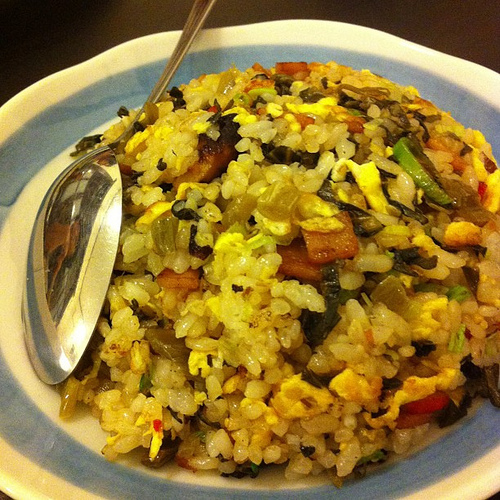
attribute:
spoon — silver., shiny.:
[22, 2, 215, 385]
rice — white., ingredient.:
[57, 60, 500, 490]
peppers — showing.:
[392, 138, 457, 208]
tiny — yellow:
[189, 351, 215, 378]